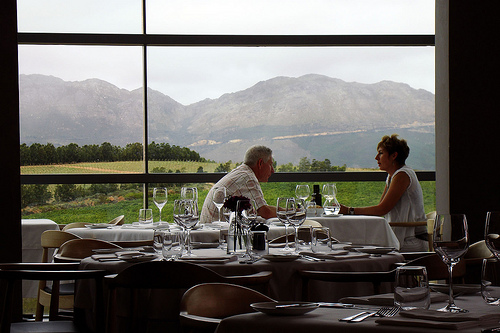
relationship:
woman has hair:
[346, 134, 429, 250] [379, 134, 410, 169]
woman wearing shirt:
[346, 134, 429, 250] [385, 169, 423, 244]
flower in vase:
[226, 194, 252, 212] [226, 214, 247, 254]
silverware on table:
[323, 302, 403, 332] [213, 284, 496, 333]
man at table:
[200, 145, 275, 219] [308, 216, 402, 251]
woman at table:
[346, 134, 429, 250] [308, 216, 402, 251]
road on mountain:
[185, 122, 431, 148] [189, 74, 437, 168]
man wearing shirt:
[200, 145, 275, 219] [200, 164, 270, 226]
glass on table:
[434, 215, 468, 312] [213, 284, 496, 333]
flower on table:
[226, 194, 252, 212] [81, 242, 407, 295]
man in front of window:
[200, 145, 275, 219] [15, 0, 435, 316]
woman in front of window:
[346, 134, 429, 250] [15, 0, 435, 316]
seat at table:
[6, 257, 101, 333] [81, 242, 407, 295]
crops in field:
[23, 161, 224, 177] [22, 158, 213, 188]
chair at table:
[33, 231, 81, 321] [69, 221, 229, 244]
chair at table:
[52, 240, 120, 323] [81, 242, 407, 295]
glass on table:
[297, 186, 312, 209] [308, 216, 402, 251]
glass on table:
[323, 183, 336, 197] [308, 216, 402, 251]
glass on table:
[152, 187, 167, 226] [69, 221, 229, 244]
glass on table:
[180, 185, 196, 203] [69, 221, 229, 244]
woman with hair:
[346, 134, 429, 250] [379, 134, 410, 169]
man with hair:
[200, 145, 275, 219] [243, 145, 271, 162]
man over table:
[200, 145, 275, 219] [308, 216, 402, 251]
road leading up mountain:
[185, 122, 431, 148] [189, 74, 437, 168]